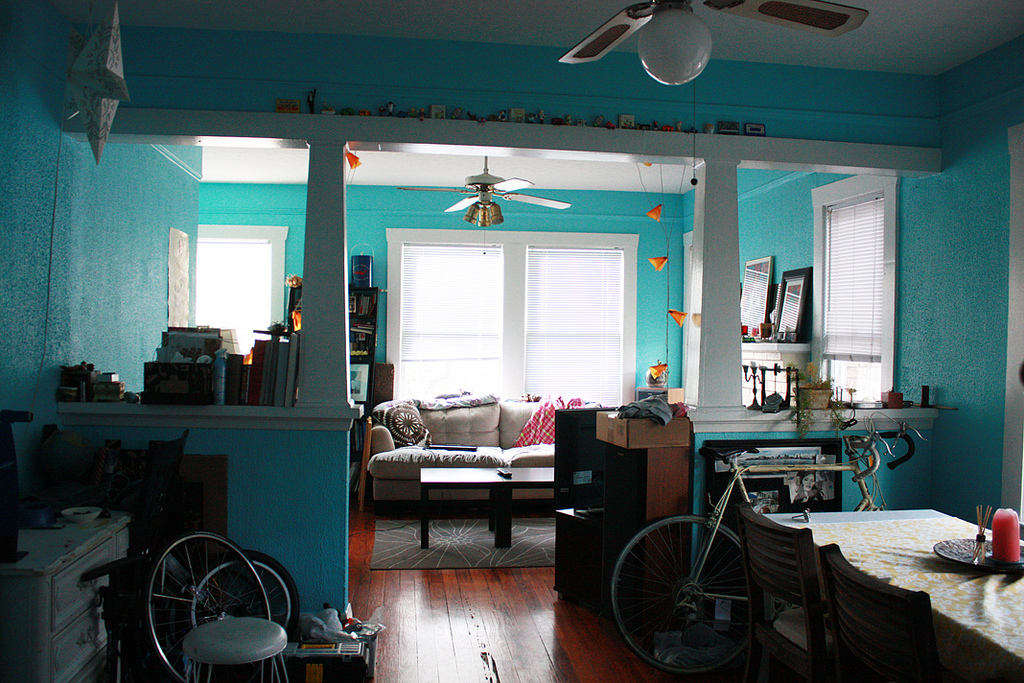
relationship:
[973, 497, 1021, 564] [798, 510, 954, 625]
candle on table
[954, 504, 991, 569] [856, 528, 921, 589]
diffuser on table